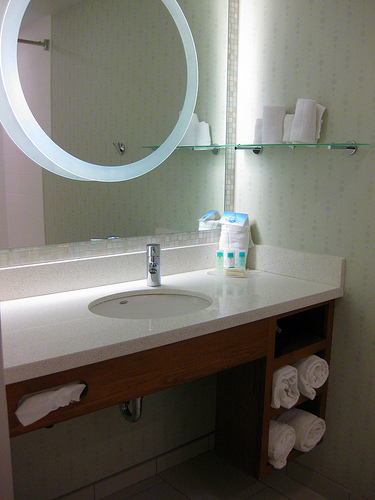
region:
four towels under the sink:
[265, 354, 361, 478]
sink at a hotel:
[3, 94, 374, 489]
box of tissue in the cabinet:
[7, 364, 148, 427]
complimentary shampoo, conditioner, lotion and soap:
[208, 205, 264, 289]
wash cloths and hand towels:
[245, 88, 347, 164]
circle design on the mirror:
[4, 6, 224, 218]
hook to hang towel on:
[85, 127, 145, 176]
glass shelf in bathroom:
[216, 127, 373, 169]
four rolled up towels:
[252, 351, 365, 483]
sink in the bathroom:
[55, 286, 233, 342]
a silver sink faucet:
[142, 238, 168, 290]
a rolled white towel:
[264, 364, 303, 412]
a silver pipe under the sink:
[114, 390, 149, 425]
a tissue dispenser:
[11, 378, 94, 431]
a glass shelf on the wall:
[202, 133, 371, 157]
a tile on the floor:
[155, 446, 268, 498]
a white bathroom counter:
[2, 237, 349, 383]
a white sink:
[83, 285, 218, 327]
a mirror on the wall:
[0, 1, 241, 296]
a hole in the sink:
[115, 295, 131, 307]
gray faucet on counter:
[123, 229, 180, 294]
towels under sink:
[251, 330, 341, 450]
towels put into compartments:
[242, 339, 339, 465]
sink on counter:
[111, 277, 220, 331]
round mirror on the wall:
[31, 13, 199, 193]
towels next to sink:
[250, 85, 329, 174]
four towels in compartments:
[252, 344, 344, 464]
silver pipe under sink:
[113, 394, 147, 441]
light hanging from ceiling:
[206, 24, 267, 109]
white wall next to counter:
[253, 168, 338, 238]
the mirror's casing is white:
[2, 0, 197, 183]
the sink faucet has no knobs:
[82, 286, 223, 344]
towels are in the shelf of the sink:
[241, 346, 351, 468]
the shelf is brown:
[5, 306, 367, 471]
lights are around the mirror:
[0, 0, 275, 304]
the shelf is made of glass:
[231, 82, 357, 177]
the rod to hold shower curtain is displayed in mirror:
[10, 20, 52, 54]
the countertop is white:
[0, 225, 367, 356]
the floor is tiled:
[123, 457, 369, 490]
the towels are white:
[261, 346, 349, 477]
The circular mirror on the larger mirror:
[1, 0, 199, 184]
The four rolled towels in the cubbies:
[266, 351, 326, 471]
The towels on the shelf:
[248, 94, 324, 148]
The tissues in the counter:
[8, 379, 88, 429]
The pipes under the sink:
[117, 397, 144, 428]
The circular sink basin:
[82, 287, 213, 321]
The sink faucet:
[143, 239, 164, 288]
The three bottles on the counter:
[213, 246, 247, 275]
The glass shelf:
[222, 141, 369, 157]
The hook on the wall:
[109, 138, 126, 157]